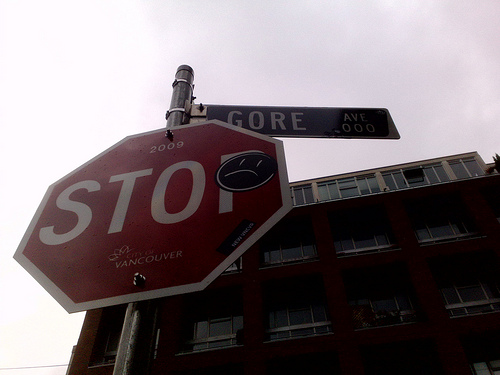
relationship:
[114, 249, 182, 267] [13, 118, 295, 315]
text on sign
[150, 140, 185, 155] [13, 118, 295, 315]
print on sign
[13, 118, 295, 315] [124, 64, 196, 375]
sign on pole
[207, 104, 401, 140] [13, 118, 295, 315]
sign above sign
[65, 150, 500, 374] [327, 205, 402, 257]
building has window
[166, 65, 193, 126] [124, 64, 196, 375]
top of pole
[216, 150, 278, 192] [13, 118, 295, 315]
sticker on sign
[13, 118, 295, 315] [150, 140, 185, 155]
sign has print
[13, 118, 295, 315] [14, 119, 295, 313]
sign has sides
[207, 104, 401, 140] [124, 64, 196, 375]
sign on pole